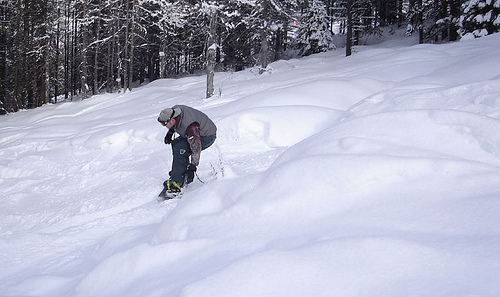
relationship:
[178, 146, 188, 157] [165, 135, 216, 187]
patch on jeans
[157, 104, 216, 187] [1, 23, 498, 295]
man snowboarding down hill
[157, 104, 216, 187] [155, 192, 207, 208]
man riding snowboard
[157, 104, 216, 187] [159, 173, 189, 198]
man on skis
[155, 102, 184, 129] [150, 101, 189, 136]
hat on head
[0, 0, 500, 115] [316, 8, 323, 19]
small tree covered snow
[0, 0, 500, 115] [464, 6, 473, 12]
small tree covered snow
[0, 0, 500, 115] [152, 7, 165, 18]
small tree covered snow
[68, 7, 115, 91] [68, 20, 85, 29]
trees covered snow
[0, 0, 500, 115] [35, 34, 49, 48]
small tree covered snow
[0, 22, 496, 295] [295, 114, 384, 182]
snow has mound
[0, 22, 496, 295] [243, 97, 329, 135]
snow has mound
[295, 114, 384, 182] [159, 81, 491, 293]
mound on hill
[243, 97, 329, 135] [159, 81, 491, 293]
mound on hill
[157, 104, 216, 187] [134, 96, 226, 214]
man in snow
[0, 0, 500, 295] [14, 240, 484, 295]
snow on ground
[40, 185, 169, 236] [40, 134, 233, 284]
tracks in snow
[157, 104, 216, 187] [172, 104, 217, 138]
man wearing jacket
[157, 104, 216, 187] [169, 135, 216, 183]
man wearing jeans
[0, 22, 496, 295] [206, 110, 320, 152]
snow has pile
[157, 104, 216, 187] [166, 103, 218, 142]
man has jacket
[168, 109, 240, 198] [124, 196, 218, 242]
man bending toward ground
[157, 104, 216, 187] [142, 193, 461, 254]
man snowbaording on snow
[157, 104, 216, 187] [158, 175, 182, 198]
man standing on snowboard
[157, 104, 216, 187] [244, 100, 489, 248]
man standing on snow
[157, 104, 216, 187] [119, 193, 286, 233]
man standing on snow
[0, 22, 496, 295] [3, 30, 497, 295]
snow covering ground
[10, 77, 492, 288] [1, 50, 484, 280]
ground covered in snow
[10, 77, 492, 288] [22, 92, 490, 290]
ground covered in snow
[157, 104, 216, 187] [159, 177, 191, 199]
man with two skis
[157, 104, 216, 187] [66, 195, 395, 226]
man going down a slope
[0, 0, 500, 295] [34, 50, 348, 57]
snow on top of trees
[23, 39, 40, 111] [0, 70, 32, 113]
small tree without snow